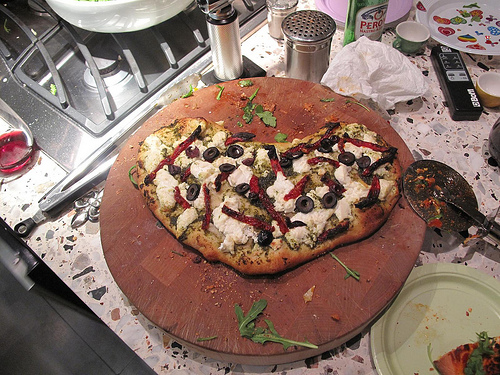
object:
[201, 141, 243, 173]
olives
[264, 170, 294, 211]
cheese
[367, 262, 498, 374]
plate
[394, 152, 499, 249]
cutter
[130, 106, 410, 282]
pizza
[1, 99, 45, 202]
glass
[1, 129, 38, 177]
wine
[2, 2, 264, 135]
burner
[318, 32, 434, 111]
napkin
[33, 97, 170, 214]
tongs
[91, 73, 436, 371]
board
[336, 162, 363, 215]
cheese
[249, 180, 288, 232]
peppers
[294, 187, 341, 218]
olives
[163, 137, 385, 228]
toppings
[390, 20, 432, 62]
green cup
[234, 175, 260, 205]
olive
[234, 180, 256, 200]
black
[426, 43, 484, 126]
tv remote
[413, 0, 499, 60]
plate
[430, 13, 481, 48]
hearts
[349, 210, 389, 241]
crust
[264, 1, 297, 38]
shaker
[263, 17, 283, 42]
salt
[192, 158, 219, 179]
cheese